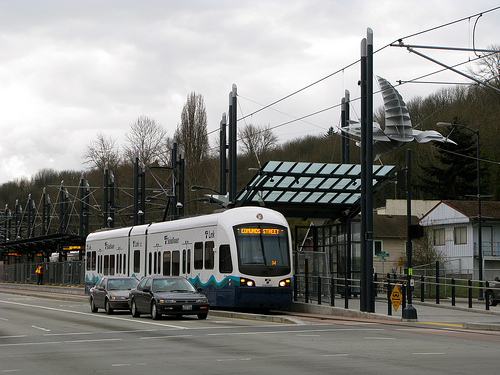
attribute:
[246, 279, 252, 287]
light — white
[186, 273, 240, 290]
wave — blue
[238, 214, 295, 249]
sign — lit, bright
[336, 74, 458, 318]
street lamp — decorative 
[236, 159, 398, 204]
roof — windowed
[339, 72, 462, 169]
sculpture — modern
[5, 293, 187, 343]
line — white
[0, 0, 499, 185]
sky — gray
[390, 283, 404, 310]
sign — yellow, black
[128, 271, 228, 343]
car — black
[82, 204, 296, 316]
train — white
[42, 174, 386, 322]
train — white